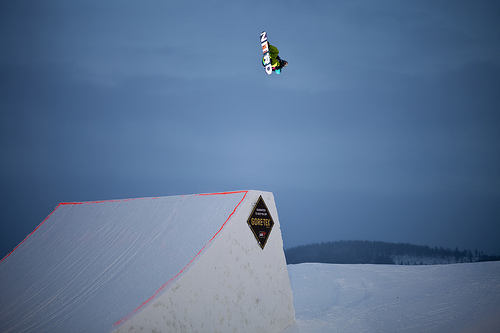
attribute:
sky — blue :
[398, 169, 477, 236]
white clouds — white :
[183, 81, 289, 140]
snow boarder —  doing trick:
[258, 30, 289, 77]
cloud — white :
[26, 125, 479, 198]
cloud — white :
[45, 0, 490, 92]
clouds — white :
[5, 1, 485, 251]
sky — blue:
[52, 31, 177, 111]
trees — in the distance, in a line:
[293, 224, 499, 267]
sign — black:
[244, 192, 277, 252]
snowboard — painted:
[258, 29, 273, 76]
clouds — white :
[314, 36, 435, 101]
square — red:
[6, 194, 270, 318]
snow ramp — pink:
[33, 185, 176, 331]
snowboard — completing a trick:
[252, 22, 297, 84]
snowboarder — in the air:
[263, 42, 288, 77]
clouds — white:
[92, 25, 154, 71]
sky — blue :
[22, 9, 492, 189]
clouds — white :
[247, 118, 498, 195]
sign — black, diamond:
[246, 195, 282, 249]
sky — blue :
[14, 46, 498, 186]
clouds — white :
[347, 65, 426, 120]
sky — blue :
[9, 19, 498, 204]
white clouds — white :
[20, 128, 137, 172]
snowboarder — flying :
[264, 40, 287, 70]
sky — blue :
[1, 2, 498, 254]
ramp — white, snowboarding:
[2, 188, 295, 330]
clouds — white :
[78, 49, 327, 103]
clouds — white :
[156, 112, 374, 188]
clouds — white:
[396, 183, 482, 224]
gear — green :
[260, 43, 286, 80]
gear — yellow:
[267, 45, 287, 69]